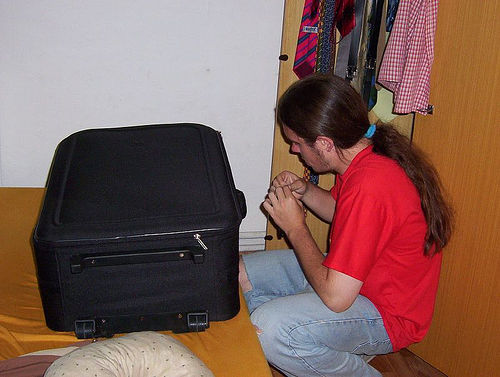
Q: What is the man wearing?
A: A red shirt.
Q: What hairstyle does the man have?
A: A long pony tail.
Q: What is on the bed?
A: A black suitcase.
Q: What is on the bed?
A: A large black suitcase.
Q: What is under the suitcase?
A: A bed.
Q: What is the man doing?
A: Kneeling on the floor.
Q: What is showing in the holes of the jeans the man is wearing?
A: Knees.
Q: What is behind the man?
A: Ties.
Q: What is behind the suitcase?
A: A wall.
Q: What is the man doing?
A: Squatting down.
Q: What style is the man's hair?
A: Long.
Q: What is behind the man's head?
A: A ponytail.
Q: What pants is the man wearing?
A: Jeans.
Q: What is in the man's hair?
A: A blue band.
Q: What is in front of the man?
A: A suitcase.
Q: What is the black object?
A: A suitcase.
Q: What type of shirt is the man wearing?
A: A t-shirt.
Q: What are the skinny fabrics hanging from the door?
A: Ties.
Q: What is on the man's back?
A: His ponytail.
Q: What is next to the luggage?
A: A pillow.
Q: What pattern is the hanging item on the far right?
A: Checkered.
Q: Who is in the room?
A: A man.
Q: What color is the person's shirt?
A: Red.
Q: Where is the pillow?
A: On the bottom left.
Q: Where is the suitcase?
A: On the bed.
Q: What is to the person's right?
A: A closet.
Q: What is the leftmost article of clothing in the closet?
A: A tie.